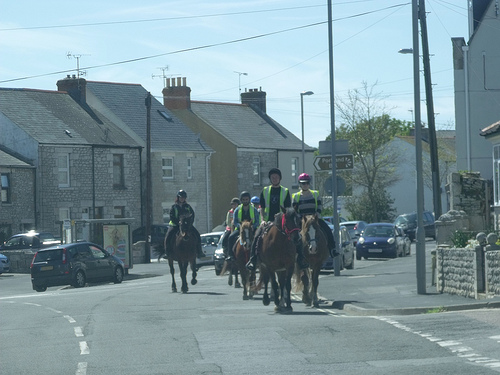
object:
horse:
[246, 200, 303, 313]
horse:
[164, 212, 202, 292]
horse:
[230, 215, 258, 302]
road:
[0, 241, 500, 374]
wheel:
[110, 263, 126, 284]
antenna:
[229, 69, 249, 93]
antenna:
[148, 61, 181, 86]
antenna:
[64, 50, 89, 79]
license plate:
[39, 264, 52, 272]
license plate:
[368, 247, 383, 252]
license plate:
[198, 255, 213, 260]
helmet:
[265, 168, 285, 183]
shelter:
[62, 214, 139, 281]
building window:
[113, 166, 125, 183]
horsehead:
[276, 203, 303, 241]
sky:
[0, 0, 470, 149]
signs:
[313, 153, 353, 172]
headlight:
[386, 236, 396, 248]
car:
[353, 219, 409, 257]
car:
[29, 242, 128, 293]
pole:
[299, 93, 306, 175]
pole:
[142, 102, 154, 264]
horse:
[294, 212, 333, 309]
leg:
[308, 267, 320, 299]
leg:
[168, 258, 177, 290]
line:
[72, 324, 87, 340]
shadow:
[179, 290, 225, 295]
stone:
[71, 154, 80, 162]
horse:
[251, 199, 300, 316]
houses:
[0, 145, 38, 247]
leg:
[188, 259, 200, 280]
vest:
[261, 182, 289, 222]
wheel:
[71, 270, 87, 286]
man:
[245, 167, 290, 268]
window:
[55, 169, 74, 185]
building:
[0, 73, 319, 259]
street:
[3, 231, 496, 372]